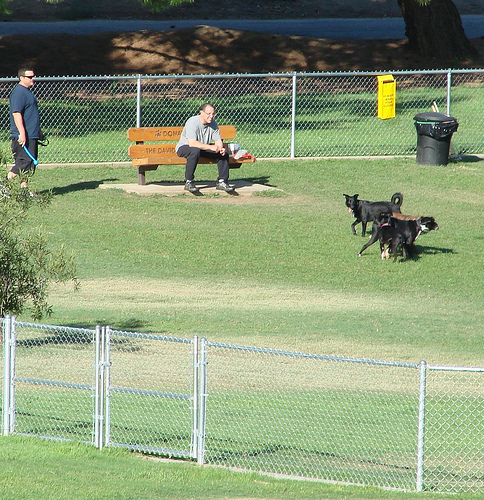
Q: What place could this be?
A: It is a field.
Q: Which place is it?
A: It is a field.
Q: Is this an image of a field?
A: Yes, it is showing a field.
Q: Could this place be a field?
A: Yes, it is a field.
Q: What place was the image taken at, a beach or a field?
A: It was taken at a field.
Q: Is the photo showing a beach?
A: No, the picture is showing a field.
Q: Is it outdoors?
A: Yes, it is outdoors.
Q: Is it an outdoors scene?
A: Yes, it is outdoors.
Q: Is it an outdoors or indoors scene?
A: It is outdoors.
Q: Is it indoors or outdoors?
A: It is outdoors.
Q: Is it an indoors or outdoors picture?
A: It is outdoors.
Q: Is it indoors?
A: No, it is outdoors.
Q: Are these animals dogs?
A: Yes, all the animals are dogs.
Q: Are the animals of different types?
A: No, all the animals are dogs.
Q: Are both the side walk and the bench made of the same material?
A: No, the side walk is made of concrete and the bench is made of wood.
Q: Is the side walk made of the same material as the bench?
A: No, the side walk is made of concrete and the bench is made of wood.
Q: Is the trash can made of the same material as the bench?
A: No, the trash can is made of plastic and the bench is made of wood.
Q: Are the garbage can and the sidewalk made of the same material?
A: No, the garbage can is made of plastic and the sidewalk is made of cement.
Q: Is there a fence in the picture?
A: Yes, there is a fence.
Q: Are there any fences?
A: Yes, there is a fence.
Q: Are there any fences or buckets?
A: Yes, there is a fence.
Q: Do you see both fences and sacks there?
A: No, there is a fence but no sacks.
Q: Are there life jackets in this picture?
A: No, there are no life jackets.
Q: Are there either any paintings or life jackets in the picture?
A: No, there are no life jackets or paintings.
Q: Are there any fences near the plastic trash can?
A: Yes, there is a fence near the trashcan.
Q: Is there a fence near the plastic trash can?
A: Yes, there is a fence near the trashcan.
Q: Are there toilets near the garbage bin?
A: No, there is a fence near the garbage bin.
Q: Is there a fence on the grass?
A: Yes, there is a fence on the grass.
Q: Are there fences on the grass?
A: Yes, there is a fence on the grass.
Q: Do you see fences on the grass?
A: Yes, there is a fence on the grass.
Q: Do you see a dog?
A: Yes, there are dogs.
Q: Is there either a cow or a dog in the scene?
A: Yes, there are dogs.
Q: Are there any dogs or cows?
A: Yes, there are dogs.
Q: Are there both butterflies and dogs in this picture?
A: No, there are dogs but no butterflies.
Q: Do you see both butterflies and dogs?
A: No, there are dogs but no butterflies.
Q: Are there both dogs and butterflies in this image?
A: No, there are dogs but no butterflies.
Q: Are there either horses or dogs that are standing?
A: Yes, the dogs are standing.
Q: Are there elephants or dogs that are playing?
A: Yes, the dogs are playing.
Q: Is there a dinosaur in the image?
A: No, there are no dinosaurs.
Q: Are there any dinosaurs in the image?
A: No, there are no dinosaurs.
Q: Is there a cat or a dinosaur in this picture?
A: No, there are no dinosaurs or cats.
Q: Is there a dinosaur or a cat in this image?
A: No, there are no dinosaurs or cats.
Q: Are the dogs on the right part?
A: Yes, the dogs are on the right of the image.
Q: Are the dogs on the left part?
A: No, the dogs are on the right of the image.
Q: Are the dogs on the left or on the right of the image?
A: The dogs are on the right of the image.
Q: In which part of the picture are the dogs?
A: The dogs are on the right of the image.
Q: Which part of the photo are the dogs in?
A: The dogs are on the right of the image.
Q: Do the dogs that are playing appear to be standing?
A: Yes, the dogs are standing.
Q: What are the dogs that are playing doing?
A: The dogs are standing.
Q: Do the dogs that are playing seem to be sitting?
A: No, the dogs are standing.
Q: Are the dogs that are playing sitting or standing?
A: The dogs are standing.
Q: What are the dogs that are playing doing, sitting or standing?
A: The dogs are standing.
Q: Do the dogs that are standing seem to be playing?
A: Yes, the dogs are playing.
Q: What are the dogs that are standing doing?
A: The dogs are playing.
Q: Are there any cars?
A: No, there are no cars.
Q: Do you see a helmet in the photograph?
A: No, there are no helmets.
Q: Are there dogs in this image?
A: Yes, there is a dog.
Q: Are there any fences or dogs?
A: Yes, there is a dog.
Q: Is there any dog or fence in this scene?
A: Yes, there is a dog.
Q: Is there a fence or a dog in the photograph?
A: Yes, there is a dog.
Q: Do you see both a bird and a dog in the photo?
A: No, there is a dog but no birds.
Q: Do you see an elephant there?
A: No, there are no elephants.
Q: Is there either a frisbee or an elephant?
A: No, there are no elephants or frisbees.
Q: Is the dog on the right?
A: Yes, the dog is on the right of the image.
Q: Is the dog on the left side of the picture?
A: No, the dog is on the right of the image.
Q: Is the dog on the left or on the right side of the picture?
A: The dog is on the right of the image.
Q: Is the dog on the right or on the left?
A: The dog is on the right of the image.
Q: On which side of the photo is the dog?
A: The dog is on the right of the image.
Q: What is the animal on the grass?
A: The animal is a dog.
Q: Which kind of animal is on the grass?
A: The animal is a dog.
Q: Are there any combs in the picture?
A: No, there are no combs.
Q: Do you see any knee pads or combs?
A: No, there are no combs or knee pads.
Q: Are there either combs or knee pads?
A: No, there are no combs or knee pads.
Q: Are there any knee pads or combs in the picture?
A: No, there are no combs or knee pads.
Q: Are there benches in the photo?
A: Yes, there is a bench.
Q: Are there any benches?
A: Yes, there is a bench.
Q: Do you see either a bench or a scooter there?
A: Yes, there is a bench.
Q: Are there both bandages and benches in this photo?
A: No, there is a bench but no bandages.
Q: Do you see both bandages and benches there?
A: No, there is a bench but no bandages.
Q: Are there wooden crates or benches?
A: Yes, there is a wood bench.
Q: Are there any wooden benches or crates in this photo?
A: Yes, there is a wood bench.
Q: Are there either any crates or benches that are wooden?
A: Yes, the bench is wooden.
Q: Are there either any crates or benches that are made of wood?
A: Yes, the bench is made of wood.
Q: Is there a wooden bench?
A: Yes, there is a wood bench.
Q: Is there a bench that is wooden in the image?
A: Yes, there is a wood bench.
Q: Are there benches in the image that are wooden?
A: Yes, there is a bench that is wooden.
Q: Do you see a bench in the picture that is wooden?
A: Yes, there is a bench that is wooden.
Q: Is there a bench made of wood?
A: Yes, there is a bench that is made of wood.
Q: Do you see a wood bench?
A: Yes, there is a bench that is made of wood.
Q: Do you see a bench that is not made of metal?
A: Yes, there is a bench that is made of wood.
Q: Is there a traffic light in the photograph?
A: No, there are no traffic lights.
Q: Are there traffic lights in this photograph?
A: No, there are no traffic lights.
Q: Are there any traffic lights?
A: No, there are no traffic lights.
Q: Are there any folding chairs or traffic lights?
A: No, there are no traffic lights or folding chairs.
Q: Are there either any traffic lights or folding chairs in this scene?
A: No, there are no traffic lights or folding chairs.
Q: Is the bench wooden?
A: Yes, the bench is wooden.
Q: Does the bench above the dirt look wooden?
A: Yes, the bench is wooden.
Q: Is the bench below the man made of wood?
A: Yes, the bench is made of wood.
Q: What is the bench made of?
A: The bench is made of wood.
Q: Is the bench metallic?
A: No, the bench is wooden.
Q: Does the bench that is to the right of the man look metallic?
A: No, the bench is wooden.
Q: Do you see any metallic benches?
A: No, there is a bench but it is wooden.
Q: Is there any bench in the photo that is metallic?
A: No, there is a bench but it is wooden.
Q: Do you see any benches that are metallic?
A: No, there is a bench but it is wooden.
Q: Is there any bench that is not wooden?
A: No, there is a bench but it is wooden.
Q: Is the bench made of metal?
A: No, the bench is made of wood.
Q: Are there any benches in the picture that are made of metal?
A: No, there is a bench but it is made of wood.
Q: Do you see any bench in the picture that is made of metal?
A: No, there is a bench but it is made of wood.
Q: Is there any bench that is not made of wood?
A: No, there is a bench but it is made of wood.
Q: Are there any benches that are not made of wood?
A: No, there is a bench but it is made of wood.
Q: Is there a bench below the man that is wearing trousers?
A: Yes, there is a bench below the man.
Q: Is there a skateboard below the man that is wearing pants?
A: No, there is a bench below the man.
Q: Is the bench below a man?
A: Yes, the bench is below a man.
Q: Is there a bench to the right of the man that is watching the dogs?
A: Yes, there is a bench to the right of the man.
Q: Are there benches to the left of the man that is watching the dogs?
A: No, the bench is to the right of the man.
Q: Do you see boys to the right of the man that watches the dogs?
A: No, there is a bench to the right of the man.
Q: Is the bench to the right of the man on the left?
A: Yes, the bench is to the right of the man.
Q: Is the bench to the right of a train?
A: No, the bench is to the right of the man.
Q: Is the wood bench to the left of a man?
A: No, the bench is to the right of a man.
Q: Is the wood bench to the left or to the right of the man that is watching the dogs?
A: The bench is to the right of the man.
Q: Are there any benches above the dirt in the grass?
A: Yes, there is a bench above the dirt.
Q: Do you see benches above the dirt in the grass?
A: Yes, there is a bench above the dirt.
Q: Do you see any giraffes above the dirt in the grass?
A: No, there is a bench above the dirt.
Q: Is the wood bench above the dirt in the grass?
A: Yes, the bench is above the dirt.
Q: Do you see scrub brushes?
A: No, there are no scrub brushes.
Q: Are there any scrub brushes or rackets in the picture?
A: No, there are no scrub brushes or rackets.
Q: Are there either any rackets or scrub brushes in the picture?
A: No, there are no scrub brushes or rackets.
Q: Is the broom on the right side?
A: Yes, the broom is on the right of the image.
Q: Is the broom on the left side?
A: No, the broom is on the right of the image.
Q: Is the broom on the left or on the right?
A: The broom is on the right of the image.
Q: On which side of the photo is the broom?
A: The broom is on the right of the image.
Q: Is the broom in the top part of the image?
A: Yes, the broom is in the top of the image.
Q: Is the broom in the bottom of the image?
A: No, the broom is in the top of the image.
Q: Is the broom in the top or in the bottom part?
A: The broom is in the top of the image.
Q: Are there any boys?
A: No, there are no boys.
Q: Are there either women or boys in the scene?
A: No, there are no boys or women.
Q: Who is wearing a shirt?
A: The man is wearing a shirt.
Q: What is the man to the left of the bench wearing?
A: The man is wearing a shirt.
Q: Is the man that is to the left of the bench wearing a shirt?
A: Yes, the man is wearing a shirt.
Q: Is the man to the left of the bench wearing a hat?
A: No, the man is wearing a shirt.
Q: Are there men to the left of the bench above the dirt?
A: Yes, there is a man to the left of the bench.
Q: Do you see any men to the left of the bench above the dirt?
A: Yes, there is a man to the left of the bench.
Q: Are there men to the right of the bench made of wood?
A: No, the man is to the left of the bench.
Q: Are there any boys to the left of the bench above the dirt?
A: No, there is a man to the left of the bench.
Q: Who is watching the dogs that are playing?
A: The man is watching the dogs.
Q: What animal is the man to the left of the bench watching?
A: The man is watching the dogs.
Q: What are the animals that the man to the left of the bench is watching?
A: The animals are dogs.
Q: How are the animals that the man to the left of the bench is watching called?
A: The animals are dogs.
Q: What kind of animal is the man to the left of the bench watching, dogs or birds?
A: The man is watching dogs.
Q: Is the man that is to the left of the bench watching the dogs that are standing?
A: Yes, the man is watching the dogs.